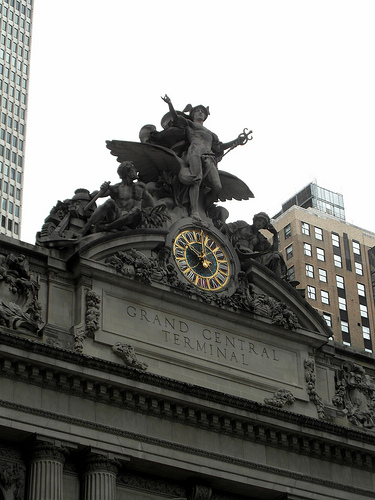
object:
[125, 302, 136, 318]
lettering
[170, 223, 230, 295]
clock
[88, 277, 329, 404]
sign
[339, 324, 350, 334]
windows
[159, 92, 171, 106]
hands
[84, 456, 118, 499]
column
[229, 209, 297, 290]
woman statue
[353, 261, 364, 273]
windows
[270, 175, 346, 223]
tall building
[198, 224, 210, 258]
hands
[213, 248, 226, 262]
numeral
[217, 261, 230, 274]
numeral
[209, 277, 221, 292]
numeral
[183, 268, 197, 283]
numeral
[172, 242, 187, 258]
numeral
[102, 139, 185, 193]
wing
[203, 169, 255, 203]
wing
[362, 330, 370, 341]
windows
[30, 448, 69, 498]
column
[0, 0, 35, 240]
building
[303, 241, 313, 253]
window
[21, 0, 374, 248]
sky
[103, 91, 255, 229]
statue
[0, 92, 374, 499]
building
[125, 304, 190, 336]
grand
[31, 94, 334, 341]
top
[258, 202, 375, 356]
building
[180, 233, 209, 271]
hands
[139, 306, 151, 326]
letters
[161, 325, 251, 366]
words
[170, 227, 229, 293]
filigree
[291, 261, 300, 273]
bricks